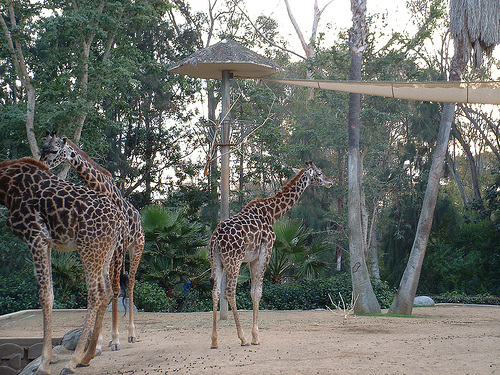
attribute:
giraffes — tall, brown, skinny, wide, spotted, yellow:
[7, 138, 333, 360]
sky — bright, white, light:
[6, 2, 499, 185]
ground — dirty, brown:
[18, 293, 499, 375]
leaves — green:
[53, 33, 143, 106]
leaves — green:
[141, 25, 201, 155]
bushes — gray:
[0, 189, 410, 315]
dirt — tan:
[257, 306, 407, 370]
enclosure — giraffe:
[2, 304, 483, 373]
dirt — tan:
[23, 311, 474, 371]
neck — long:
[255, 169, 313, 224]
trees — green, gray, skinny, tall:
[0, 3, 468, 295]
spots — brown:
[19, 162, 132, 243]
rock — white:
[412, 289, 439, 309]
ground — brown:
[125, 315, 478, 371]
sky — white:
[267, 0, 447, 60]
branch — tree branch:
[130, 10, 230, 56]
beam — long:
[218, 69, 235, 319]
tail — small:
[111, 210, 133, 324]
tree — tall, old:
[335, 6, 487, 322]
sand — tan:
[269, 328, 498, 373]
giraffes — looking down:
[3, 112, 341, 349]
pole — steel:
[212, 68, 245, 218]